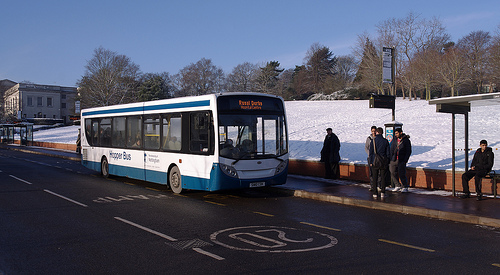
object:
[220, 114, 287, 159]
glass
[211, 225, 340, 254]
circle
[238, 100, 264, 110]
display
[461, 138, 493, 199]
man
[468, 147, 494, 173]
black jacket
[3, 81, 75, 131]
building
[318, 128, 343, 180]
people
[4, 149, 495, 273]
road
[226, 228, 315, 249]
number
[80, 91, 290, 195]
bus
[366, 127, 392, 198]
passengers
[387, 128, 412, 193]
man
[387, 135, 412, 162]
jacket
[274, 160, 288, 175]
light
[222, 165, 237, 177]
light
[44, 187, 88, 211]
line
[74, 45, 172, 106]
trees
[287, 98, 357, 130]
snow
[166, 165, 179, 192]
wheels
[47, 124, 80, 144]
snow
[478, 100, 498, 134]
snow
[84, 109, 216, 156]
windows